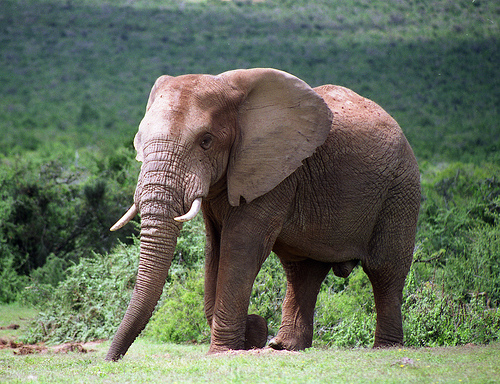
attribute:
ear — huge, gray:
[223, 63, 329, 220]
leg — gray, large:
[206, 224, 268, 346]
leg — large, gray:
[275, 257, 321, 359]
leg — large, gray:
[364, 175, 411, 345]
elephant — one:
[124, 69, 419, 338]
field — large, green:
[27, 354, 497, 380]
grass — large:
[19, 331, 495, 381]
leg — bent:
[199, 296, 275, 359]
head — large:
[52, 64, 332, 374]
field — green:
[0, 291, 497, 381]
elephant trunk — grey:
[103, 190, 189, 362]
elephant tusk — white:
[172, 198, 202, 223]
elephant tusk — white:
[105, 199, 133, 236]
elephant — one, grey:
[106, 62, 424, 351]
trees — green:
[0, 136, 495, 340]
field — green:
[5, 311, 497, 380]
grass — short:
[1, 338, 499, 382]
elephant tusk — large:
[103, 198, 152, 232]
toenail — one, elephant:
[264, 336, 291, 354]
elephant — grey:
[80, 44, 425, 350]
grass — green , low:
[0, 278, 490, 379]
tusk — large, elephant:
[163, 189, 207, 239]